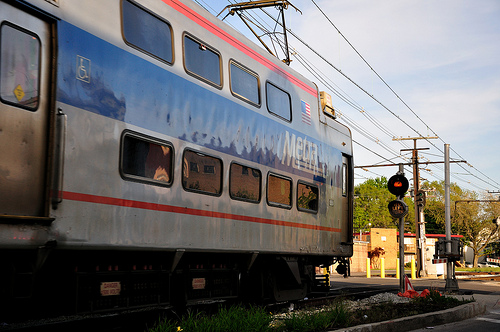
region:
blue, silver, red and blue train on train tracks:
[2, 0, 362, 326]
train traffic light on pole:
[374, 158, 423, 295]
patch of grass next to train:
[115, 294, 359, 329]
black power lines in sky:
[202, 0, 497, 210]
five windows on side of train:
[108, 115, 330, 217]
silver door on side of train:
[6, 1, 75, 236]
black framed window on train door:
[3, 15, 47, 122]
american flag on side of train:
[296, 95, 316, 129]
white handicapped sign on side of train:
[68, 43, 100, 93]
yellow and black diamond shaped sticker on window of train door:
[5, 76, 32, 103]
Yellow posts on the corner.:
[361, 247, 431, 282]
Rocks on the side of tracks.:
[357, 293, 422, 314]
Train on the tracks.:
[65, 90, 398, 285]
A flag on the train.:
[292, 98, 313, 126]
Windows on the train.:
[108, 118, 352, 232]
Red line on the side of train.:
[78, 187, 353, 231]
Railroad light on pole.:
[377, 163, 413, 263]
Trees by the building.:
[418, 176, 493, 273]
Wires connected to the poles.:
[276, 20, 441, 160]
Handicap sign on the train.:
[66, 47, 98, 94]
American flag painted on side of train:
[293, 95, 315, 134]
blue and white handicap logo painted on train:
[70, 49, 105, 92]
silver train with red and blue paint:
[11, 2, 364, 315]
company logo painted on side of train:
[274, 124, 334, 184]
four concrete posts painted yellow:
[361, 247, 423, 280]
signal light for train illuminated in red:
[383, 157, 416, 297]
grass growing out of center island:
[201, 297, 443, 329]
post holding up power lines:
[309, 30, 446, 287]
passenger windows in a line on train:
[102, 127, 324, 221]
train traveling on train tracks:
[230, 268, 396, 315]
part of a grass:
[318, 302, 339, 316]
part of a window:
[183, 153, 230, 223]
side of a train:
[203, 169, 260, 237]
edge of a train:
[261, 234, 285, 256]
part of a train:
[191, 175, 215, 212]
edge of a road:
[453, 305, 468, 317]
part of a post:
[403, 192, 420, 224]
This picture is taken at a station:
[15, 24, 475, 307]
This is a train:
[45, 38, 337, 280]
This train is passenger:
[44, 38, 409, 318]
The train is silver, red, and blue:
[29, 20, 364, 311]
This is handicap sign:
[59, 43, 118, 110]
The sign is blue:
[42, 41, 117, 106]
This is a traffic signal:
[369, 145, 495, 250]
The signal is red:
[377, 172, 444, 224]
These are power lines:
[322, 64, 492, 214]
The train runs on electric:
[197, 21, 434, 145]